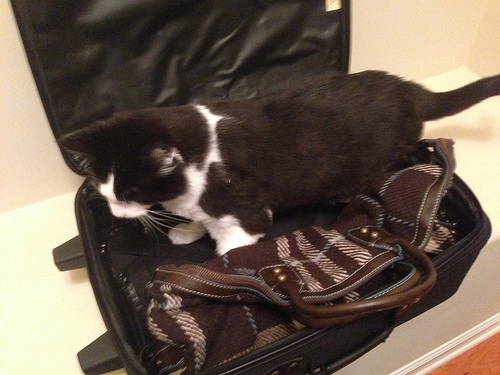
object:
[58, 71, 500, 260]
cat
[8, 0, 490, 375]
suit case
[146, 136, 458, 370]
purse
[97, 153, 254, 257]
white part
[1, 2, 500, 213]
wall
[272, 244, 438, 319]
handle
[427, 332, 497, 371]
wood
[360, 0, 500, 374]
side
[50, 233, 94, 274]
leg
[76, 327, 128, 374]
leg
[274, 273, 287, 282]
button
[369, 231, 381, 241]
button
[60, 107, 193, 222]
head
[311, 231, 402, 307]
flap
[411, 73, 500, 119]
tail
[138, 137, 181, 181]
ear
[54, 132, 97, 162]
ear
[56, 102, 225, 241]
hair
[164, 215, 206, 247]
paws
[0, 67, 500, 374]
table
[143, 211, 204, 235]
whiskers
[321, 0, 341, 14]
tag